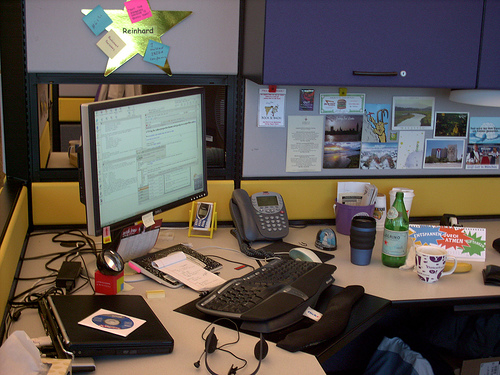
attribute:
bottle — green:
[381, 190, 409, 269]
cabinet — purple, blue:
[239, 0, 481, 89]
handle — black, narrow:
[352, 69, 400, 77]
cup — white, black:
[415, 246, 457, 284]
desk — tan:
[1, 219, 499, 375]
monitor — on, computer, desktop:
[76, 86, 208, 238]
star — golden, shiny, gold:
[80, 0, 193, 79]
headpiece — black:
[194, 316, 269, 374]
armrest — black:
[276, 284, 364, 354]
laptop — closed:
[47, 293, 175, 356]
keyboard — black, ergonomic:
[194, 257, 338, 321]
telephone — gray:
[228, 187, 291, 243]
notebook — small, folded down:
[151, 250, 228, 293]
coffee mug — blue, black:
[347, 214, 376, 265]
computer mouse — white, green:
[287, 246, 323, 265]